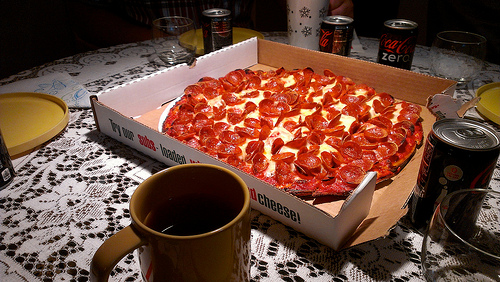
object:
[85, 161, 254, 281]
mug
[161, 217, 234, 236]
liquid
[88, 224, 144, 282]
handle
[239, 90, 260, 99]
pepperoni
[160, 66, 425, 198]
pizza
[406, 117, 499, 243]
can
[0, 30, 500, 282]
table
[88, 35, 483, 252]
box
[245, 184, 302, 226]
lettering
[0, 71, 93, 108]
napkin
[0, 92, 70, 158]
plate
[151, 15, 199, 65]
glass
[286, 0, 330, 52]
cup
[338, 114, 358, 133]
cheese